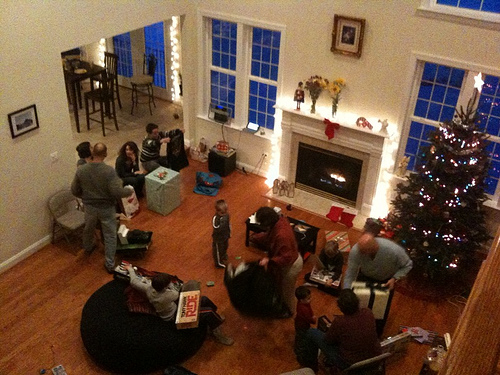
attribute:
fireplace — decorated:
[269, 96, 394, 226]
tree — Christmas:
[373, 70, 493, 300]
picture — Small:
[9, 108, 38, 126]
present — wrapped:
[348, 277, 400, 326]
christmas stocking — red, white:
[338, 205, 358, 228]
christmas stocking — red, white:
[327, 202, 344, 226]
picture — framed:
[3, 89, 47, 154]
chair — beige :
[43, 182, 95, 254]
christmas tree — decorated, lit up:
[358, 72, 495, 310]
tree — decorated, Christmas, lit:
[382, 84, 495, 283]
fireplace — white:
[261, 99, 389, 234]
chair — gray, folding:
[44, 189, 89, 248]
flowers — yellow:
[320, 76, 355, 121]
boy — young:
[211, 194, 233, 270]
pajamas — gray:
[210, 212, 230, 265]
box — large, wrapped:
[140, 164, 187, 219]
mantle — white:
[275, 99, 400, 139]